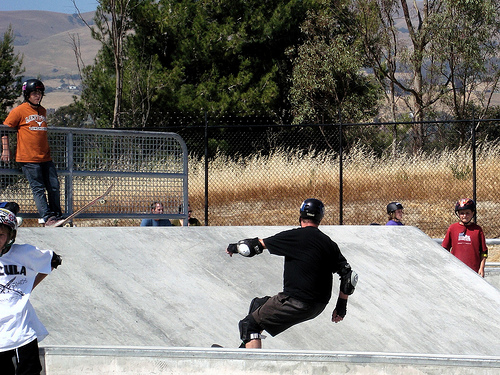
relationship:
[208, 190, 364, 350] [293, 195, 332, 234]
skater wear helmets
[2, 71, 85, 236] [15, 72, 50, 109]
skater wears helmets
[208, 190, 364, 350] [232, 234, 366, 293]
skate boarder wearing elbow pads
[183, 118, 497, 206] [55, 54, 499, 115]
fence located in background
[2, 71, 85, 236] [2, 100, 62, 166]
skate boarder wearing orange shirt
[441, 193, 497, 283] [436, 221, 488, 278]
boy wearing red shirt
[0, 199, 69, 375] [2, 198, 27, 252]
man wearing blue helmet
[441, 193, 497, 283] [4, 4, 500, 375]
boy watching in photo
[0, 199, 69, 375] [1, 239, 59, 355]
person wearing a white shirt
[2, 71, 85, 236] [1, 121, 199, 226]
person leaning against fence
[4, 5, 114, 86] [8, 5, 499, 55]
mountains in background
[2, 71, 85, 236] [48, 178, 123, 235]
man standing on end skateboard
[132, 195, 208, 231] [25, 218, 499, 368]
people gathered around skating ramp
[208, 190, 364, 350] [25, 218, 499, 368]
man using skate ramp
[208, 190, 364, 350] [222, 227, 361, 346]
man wearing black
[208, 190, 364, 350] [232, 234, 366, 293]
skateboarder wearing protective gear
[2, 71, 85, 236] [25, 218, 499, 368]
skateboarder waits at top ramp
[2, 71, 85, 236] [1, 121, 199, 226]
skateboarder leans on railing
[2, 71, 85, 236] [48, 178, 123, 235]
boy holds skateboard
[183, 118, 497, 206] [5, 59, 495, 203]
fence surrounds area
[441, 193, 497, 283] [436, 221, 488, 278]
kid wearing red shirt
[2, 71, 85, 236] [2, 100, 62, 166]
boy wearing orange shirt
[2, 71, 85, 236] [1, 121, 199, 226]
boy leaning on fence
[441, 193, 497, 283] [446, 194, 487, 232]
boy wearing helmet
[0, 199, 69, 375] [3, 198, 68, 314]
person holding back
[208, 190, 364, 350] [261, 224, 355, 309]
skater wearing black shirt